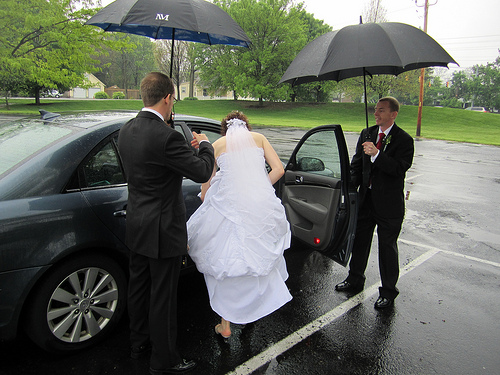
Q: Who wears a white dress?
A: A woman.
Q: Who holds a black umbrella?
A: A short man.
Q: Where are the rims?
A: In the tire.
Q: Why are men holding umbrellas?
A: It is raining.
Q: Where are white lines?
A: On the ground.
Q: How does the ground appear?
A: Wet.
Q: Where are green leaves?
A: On the trees.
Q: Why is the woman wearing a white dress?
A: Woman is a bride.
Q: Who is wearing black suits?
A: Two men.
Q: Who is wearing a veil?
A: The bride.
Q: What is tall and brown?
A: Telephone pole.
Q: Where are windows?
A: On a car.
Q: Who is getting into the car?
A: A bride.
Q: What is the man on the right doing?
A: Holding open the car door.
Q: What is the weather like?
A: It's raining.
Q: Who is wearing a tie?
A: The man on the right.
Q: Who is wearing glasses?
A: The man on the left.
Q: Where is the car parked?
A: In a parking lot.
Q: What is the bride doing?
A: Getting into the car.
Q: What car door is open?
A: Front right door on the passsenger side.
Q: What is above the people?
A: Umbrellas.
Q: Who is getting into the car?
A: A bride.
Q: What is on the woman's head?
A: A veil.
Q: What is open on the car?
A: The passenger door.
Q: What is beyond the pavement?
A: Grass.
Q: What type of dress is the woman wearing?
A: A wedding dress.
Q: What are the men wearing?
A: Suits.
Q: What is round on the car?
A: The back tire.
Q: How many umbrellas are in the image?
A: Two.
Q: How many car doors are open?
A: One.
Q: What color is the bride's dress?
A: White.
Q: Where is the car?
A: Parking lot.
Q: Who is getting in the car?
A: The bride.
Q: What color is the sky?
A: White.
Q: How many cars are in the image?
A: One.